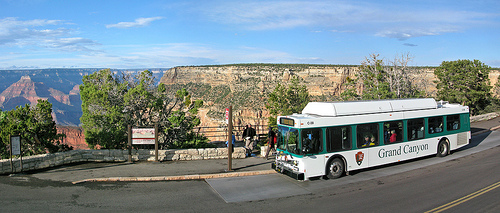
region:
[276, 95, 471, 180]
white bus is stopped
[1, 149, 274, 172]
low stone wall behind the bus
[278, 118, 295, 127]
destination window above windshield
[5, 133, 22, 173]
sign in front of wall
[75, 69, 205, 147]
tree top visible behind wall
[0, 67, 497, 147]
grand canyon visible behind bus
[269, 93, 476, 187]
large white tour bus with green trim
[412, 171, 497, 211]
double yellow line painted on road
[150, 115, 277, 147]
metal handrail on top of stone wall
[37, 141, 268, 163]
short stone wall under handrail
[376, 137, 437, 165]
black printed Grand Canyon on side of bus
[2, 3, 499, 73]
blue sky with scattered gray clouds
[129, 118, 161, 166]
tourist imformation sign on sidewalk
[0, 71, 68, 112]
view of pillar of red rock in canyon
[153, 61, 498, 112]
light brown plateau peppered with vegetation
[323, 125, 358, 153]
large wide passenger window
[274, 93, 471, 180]
bus is white and green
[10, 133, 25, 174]
small wooden sign by wall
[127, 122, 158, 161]
large wooden sign by wall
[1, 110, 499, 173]
rock stone wall behind bus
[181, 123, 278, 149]
railing fence behind people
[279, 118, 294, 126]
led sign on bus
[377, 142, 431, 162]
sign on bus says Grand Canyon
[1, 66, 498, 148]
large canyon mountains behind wall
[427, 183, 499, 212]
yellow paint strips on road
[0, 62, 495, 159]
Rocky canyon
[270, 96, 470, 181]
Bus filled with people.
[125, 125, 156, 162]
Descriptive sign on a sidewalk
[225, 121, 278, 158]
People waiting at the bus stop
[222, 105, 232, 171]
Bus stop sign on a sidewalk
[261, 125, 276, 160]
Man walking near a bus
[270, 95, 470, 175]
Grand Canyon bus stopped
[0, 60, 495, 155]
Grand canyon scenery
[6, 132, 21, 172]
Grand Canyon sign near stone wall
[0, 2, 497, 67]
clouds in blue sky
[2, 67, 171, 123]
hazy valley of canyon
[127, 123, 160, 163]
sign on two posts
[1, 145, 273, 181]
side of stone walls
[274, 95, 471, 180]
side of tourist bus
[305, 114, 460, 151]
windows on side of bus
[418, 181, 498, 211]
double yellow lines on street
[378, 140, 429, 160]
two words on bus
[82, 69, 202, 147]
green leaves on trees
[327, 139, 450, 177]
tires on side of bus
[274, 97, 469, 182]
a white and green tour bus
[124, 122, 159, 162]
a tourist information sign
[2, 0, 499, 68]
a cloudy blue sky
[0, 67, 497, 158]
at the Grand Canyon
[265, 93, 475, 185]
green and white bus parked next to sidewalk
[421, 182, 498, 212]
double yellow lines painted in middle of street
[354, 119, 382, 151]
window on side of bus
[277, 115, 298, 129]
digital window at top of front of bus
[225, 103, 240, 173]
wooden pole on sidewalk in front of bus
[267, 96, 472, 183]
white and green tour bus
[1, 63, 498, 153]
large view of the Grand Canyon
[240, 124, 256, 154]
man looking out over the Grand Canyon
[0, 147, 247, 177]
short stone wall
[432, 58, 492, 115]
green roadside tree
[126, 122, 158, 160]
sign held up by two wood poles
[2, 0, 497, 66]
blue sky with wispy clouds